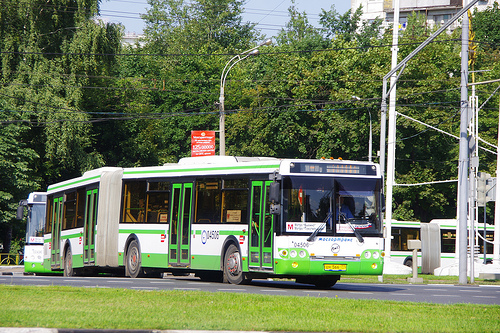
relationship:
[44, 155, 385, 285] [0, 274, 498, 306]
bus riding on street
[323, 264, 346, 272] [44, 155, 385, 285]
license plate on bus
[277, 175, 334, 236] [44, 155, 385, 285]
windshield on bus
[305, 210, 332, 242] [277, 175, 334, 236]
wiper on windshield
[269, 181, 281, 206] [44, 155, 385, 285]
mirror on side of bus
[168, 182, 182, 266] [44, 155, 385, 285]
door on side of bus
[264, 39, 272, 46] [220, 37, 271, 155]
light on pole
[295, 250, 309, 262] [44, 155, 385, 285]
headlight on bus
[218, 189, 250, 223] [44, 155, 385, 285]
window on side of bus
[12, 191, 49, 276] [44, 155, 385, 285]
bus behind bus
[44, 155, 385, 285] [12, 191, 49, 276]
bus in front of bus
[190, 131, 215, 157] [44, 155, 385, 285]
sign behind bus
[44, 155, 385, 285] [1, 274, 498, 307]
bus driving on road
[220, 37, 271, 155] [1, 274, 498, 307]
pole next to road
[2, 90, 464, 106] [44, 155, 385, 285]
power line above bus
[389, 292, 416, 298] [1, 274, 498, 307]
white mark on road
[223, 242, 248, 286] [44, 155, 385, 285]
wheel on bus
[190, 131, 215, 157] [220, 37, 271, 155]
sign on pole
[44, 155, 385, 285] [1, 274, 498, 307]
bus on road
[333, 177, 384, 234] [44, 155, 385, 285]
windshield on front of bus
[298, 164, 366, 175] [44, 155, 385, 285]
marquee on front of bus